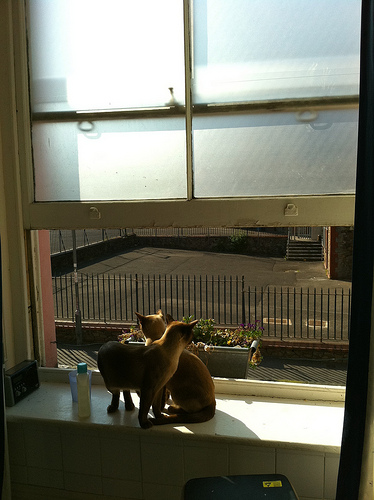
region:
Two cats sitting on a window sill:
[100, 312, 239, 445]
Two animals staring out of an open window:
[75, 303, 253, 434]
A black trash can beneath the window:
[188, 468, 301, 498]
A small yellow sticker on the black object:
[258, 478, 284, 491]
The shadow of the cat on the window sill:
[160, 410, 267, 446]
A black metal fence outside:
[48, 268, 346, 337]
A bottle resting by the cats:
[73, 361, 95, 417]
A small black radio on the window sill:
[4, 360, 49, 401]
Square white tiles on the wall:
[58, 442, 165, 489]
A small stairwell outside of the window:
[285, 240, 333, 262]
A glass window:
[193, 107, 360, 197]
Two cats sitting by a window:
[97, 310, 216, 424]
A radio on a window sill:
[3, 358, 40, 407]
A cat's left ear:
[165, 313, 171, 322]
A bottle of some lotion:
[74, 362, 91, 415]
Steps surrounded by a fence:
[286, 240, 321, 257]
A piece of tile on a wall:
[100, 437, 142, 480]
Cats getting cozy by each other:
[98, 311, 216, 423]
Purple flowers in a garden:
[237, 321, 262, 345]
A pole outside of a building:
[73, 228, 81, 347]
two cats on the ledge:
[92, 312, 232, 437]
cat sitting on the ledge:
[136, 307, 226, 422]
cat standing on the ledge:
[93, 315, 206, 430]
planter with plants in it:
[111, 305, 261, 388]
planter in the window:
[113, 313, 271, 385]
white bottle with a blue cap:
[72, 362, 100, 420]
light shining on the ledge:
[248, 398, 350, 451]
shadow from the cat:
[189, 403, 258, 452]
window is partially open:
[12, 4, 372, 387]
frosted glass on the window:
[28, 7, 360, 195]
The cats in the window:
[93, 305, 219, 431]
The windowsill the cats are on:
[8, 370, 346, 457]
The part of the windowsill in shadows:
[1, 372, 157, 428]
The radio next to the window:
[1, 355, 45, 405]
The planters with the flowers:
[114, 317, 269, 386]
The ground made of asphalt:
[49, 229, 348, 388]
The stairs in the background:
[283, 237, 327, 264]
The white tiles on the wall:
[6, 414, 340, 499]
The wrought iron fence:
[51, 267, 352, 341]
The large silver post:
[68, 228, 86, 346]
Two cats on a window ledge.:
[27, 224, 338, 424]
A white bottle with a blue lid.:
[66, 359, 95, 411]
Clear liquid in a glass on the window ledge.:
[72, 364, 92, 403]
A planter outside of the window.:
[119, 328, 255, 373]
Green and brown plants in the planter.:
[116, 312, 261, 347]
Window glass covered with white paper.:
[20, 0, 353, 193]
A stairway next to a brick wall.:
[284, 236, 320, 264]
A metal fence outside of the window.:
[53, 268, 350, 337]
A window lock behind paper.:
[156, 82, 183, 106]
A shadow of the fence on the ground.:
[50, 343, 347, 384]